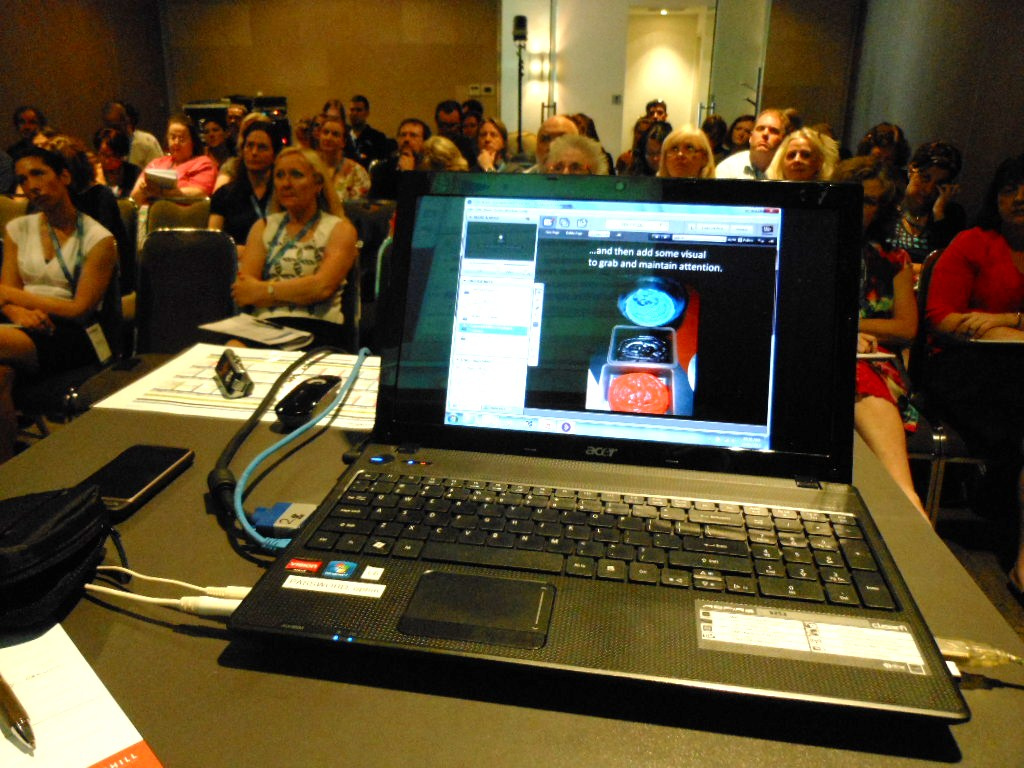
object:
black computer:
[370, 171, 862, 485]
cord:
[82, 565, 253, 617]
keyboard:
[302, 470, 897, 611]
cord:
[206, 346, 373, 569]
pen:
[0, 672, 36, 752]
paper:
[0, 623, 167, 768]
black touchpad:
[397, 570, 558, 650]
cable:
[935, 637, 1024, 688]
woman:
[233, 147, 357, 347]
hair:
[274, 143, 345, 220]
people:
[230, 146, 359, 352]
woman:
[131, 113, 219, 203]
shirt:
[130, 155, 219, 204]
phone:
[75, 444, 196, 515]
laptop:
[226, 168, 972, 724]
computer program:
[443, 195, 782, 450]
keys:
[486, 532, 516, 549]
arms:
[230, 216, 359, 307]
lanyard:
[262, 208, 321, 281]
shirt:
[252, 209, 349, 325]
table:
[0, 344, 1024, 768]